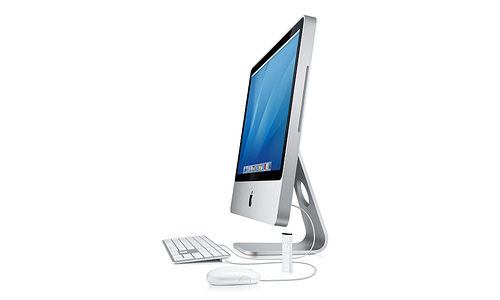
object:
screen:
[232, 26, 302, 182]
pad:
[179, 248, 200, 256]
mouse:
[206, 262, 258, 288]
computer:
[231, 20, 321, 226]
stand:
[290, 158, 345, 254]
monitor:
[227, 16, 310, 226]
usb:
[282, 201, 290, 207]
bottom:
[229, 181, 297, 227]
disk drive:
[296, 65, 312, 135]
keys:
[201, 240, 205, 243]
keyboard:
[161, 234, 230, 264]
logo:
[245, 184, 253, 210]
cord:
[291, 205, 317, 259]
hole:
[293, 179, 313, 209]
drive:
[280, 228, 294, 275]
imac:
[163, 15, 327, 261]